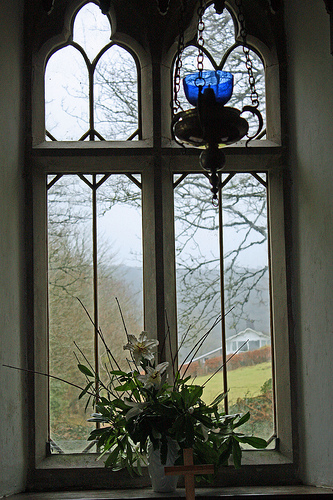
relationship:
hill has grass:
[177, 354, 270, 445] [183, 361, 273, 411]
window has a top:
[39, 5, 275, 450] [41, 5, 140, 142]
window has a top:
[41, 7, 143, 141] [41, 5, 140, 142]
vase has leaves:
[148, 437, 183, 491] [180, 387, 220, 428]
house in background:
[230, 326, 263, 354] [48, 179, 279, 454]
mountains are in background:
[92, 264, 270, 362] [48, 179, 279, 454]